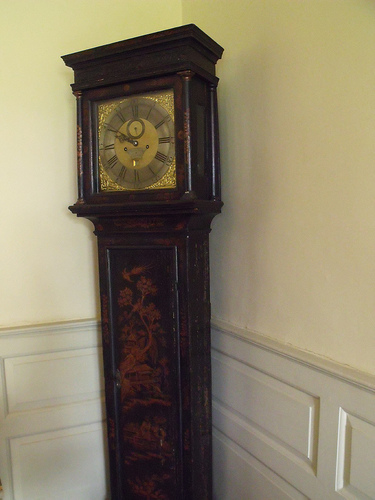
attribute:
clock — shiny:
[92, 100, 175, 189]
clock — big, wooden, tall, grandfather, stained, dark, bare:
[58, 23, 225, 498]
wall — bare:
[2, 2, 373, 378]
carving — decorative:
[111, 262, 188, 498]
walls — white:
[3, 3, 371, 471]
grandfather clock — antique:
[60, 18, 226, 498]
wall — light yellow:
[179, 1, 372, 376]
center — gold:
[131, 139, 140, 146]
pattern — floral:
[92, 248, 179, 499]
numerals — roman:
[99, 99, 173, 187]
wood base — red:
[68, 69, 224, 217]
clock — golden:
[95, 99, 182, 192]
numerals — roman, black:
[96, 98, 187, 186]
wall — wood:
[214, 108, 373, 366]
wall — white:
[210, 322, 373, 498]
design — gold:
[112, 264, 178, 499]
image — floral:
[115, 253, 170, 497]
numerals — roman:
[130, 102, 172, 183]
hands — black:
[110, 126, 138, 149]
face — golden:
[97, 95, 178, 190]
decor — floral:
[105, 239, 190, 496]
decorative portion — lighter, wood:
[105, 246, 181, 498]